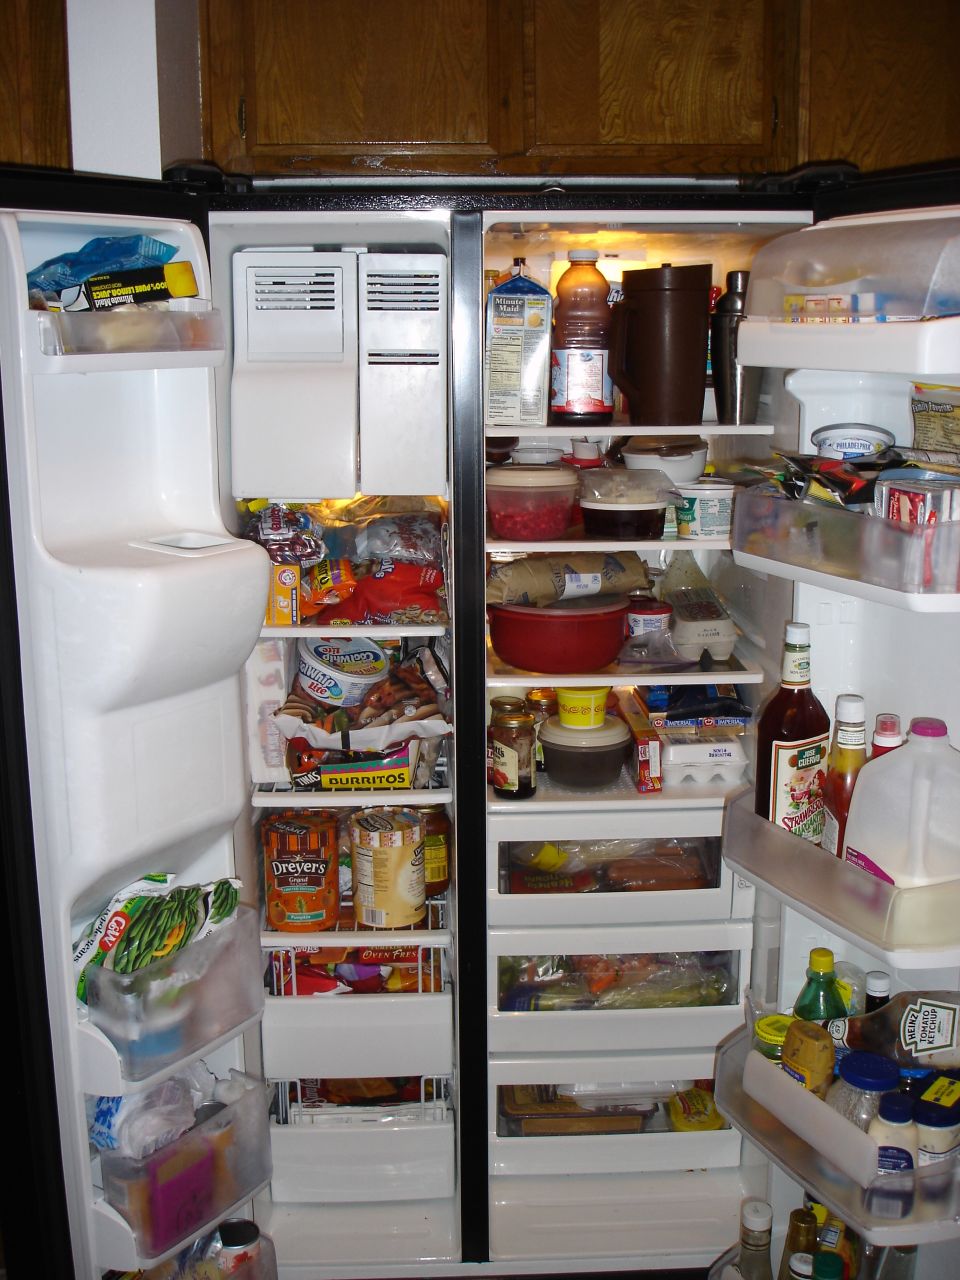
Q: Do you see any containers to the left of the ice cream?
A: Yes, there is a container to the left of the ice cream.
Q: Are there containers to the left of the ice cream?
A: Yes, there is a container to the left of the ice cream.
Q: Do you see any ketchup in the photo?
A: Yes, there is ketchup.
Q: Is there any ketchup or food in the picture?
A: Yes, there is ketchup.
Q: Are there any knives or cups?
A: No, there are no cups or knives.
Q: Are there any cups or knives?
A: No, there are no cups or knives.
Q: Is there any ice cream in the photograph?
A: Yes, there is ice cream.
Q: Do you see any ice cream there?
A: Yes, there is ice cream.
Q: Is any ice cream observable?
A: Yes, there is ice cream.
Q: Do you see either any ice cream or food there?
A: Yes, there is ice cream.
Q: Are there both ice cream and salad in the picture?
A: No, there is ice cream but no salad.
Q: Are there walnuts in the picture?
A: No, there are no walnuts.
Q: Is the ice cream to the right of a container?
A: Yes, the ice cream is to the right of a container.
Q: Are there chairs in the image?
A: No, there are no chairs.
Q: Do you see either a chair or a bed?
A: No, there are no chairs or beds.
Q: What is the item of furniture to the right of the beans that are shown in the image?
A: The piece of furniture is a shelf.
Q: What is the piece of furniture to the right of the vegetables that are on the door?
A: The piece of furniture is a shelf.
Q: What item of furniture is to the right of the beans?
A: The piece of furniture is a shelf.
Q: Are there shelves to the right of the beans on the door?
A: Yes, there is a shelf to the right of the beans.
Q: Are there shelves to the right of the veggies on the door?
A: Yes, there is a shelf to the right of the beans.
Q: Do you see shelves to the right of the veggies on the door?
A: Yes, there is a shelf to the right of the beans.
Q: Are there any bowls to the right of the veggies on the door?
A: No, there is a shelf to the right of the beans.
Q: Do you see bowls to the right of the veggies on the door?
A: No, there is a shelf to the right of the beans.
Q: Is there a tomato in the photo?
A: No, there are no tomatoes.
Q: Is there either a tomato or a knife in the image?
A: No, there are no tomatoes or knives.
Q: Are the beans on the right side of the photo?
A: No, the beans are on the left of the image.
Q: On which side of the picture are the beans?
A: The beans are on the left of the image.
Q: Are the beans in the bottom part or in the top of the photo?
A: The beans are in the bottom of the image.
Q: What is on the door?
A: The beans are on the door.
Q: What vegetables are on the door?
A: The vegetables are beans.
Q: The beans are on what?
A: The beans are on the door.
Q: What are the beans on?
A: The beans are on the door.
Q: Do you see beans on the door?
A: Yes, there are beans on the door.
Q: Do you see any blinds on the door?
A: No, there are beans on the door.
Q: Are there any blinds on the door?
A: No, there are beans on the door.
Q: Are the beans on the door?
A: Yes, the beans are on the door.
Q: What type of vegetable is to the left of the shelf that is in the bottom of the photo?
A: The vegetables are beans.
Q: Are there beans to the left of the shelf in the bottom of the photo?
A: Yes, there are beans to the left of the shelf.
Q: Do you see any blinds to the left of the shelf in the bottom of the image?
A: No, there are beans to the left of the shelf.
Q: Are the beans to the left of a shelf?
A: Yes, the beans are to the left of a shelf.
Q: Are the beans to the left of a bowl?
A: No, the beans are to the left of a shelf.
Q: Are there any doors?
A: Yes, there is a door.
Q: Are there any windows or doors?
A: Yes, there is a door.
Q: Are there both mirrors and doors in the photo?
A: No, there is a door but no mirrors.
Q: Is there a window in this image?
A: No, there are no windows.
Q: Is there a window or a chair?
A: No, there are no windows or chairs.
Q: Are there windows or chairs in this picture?
A: No, there are no windows or chairs.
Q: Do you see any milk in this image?
A: Yes, there is milk.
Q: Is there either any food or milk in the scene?
A: Yes, there is milk.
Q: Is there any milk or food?
A: Yes, there is milk.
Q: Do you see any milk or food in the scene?
A: Yes, there is milk.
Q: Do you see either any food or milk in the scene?
A: Yes, there is milk.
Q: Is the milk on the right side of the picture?
A: Yes, the milk is on the right of the image.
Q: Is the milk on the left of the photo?
A: No, the milk is on the right of the image.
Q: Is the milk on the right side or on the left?
A: The milk is on the right of the image.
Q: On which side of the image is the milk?
A: The milk is on the right of the image.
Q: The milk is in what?
A: The milk is in the freezer.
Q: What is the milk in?
A: The milk is in the freezer.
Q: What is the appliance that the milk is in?
A: The appliance is a refrigerator.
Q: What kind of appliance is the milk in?
A: The milk is in the freezer.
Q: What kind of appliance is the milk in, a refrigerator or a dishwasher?
A: The milk is in a refrigerator.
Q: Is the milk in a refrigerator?
A: Yes, the milk is in a refrigerator.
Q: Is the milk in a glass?
A: No, the milk is in a refrigerator.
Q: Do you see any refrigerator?
A: Yes, there is a refrigerator.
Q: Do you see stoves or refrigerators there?
A: Yes, there is a refrigerator.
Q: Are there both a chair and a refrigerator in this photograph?
A: No, there is a refrigerator but no chairs.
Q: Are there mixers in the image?
A: No, there are no mixers.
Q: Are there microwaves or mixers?
A: No, there are no mixers or microwaves.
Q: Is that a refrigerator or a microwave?
A: That is a refrigerator.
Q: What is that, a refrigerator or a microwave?
A: That is a refrigerator.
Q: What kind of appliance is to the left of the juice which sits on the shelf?
A: The appliance is a refrigerator.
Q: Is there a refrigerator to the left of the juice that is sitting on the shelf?
A: Yes, there is a refrigerator to the left of the juice.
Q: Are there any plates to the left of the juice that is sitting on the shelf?
A: No, there is a refrigerator to the left of the juice.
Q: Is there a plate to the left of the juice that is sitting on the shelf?
A: No, there is a refrigerator to the left of the juice.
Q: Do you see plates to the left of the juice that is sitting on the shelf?
A: No, there is a refrigerator to the left of the juice.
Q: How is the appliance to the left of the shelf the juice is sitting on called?
A: The appliance is a refrigerator.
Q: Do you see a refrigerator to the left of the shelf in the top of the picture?
A: Yes, there is a refrigerator to the left of the shelf.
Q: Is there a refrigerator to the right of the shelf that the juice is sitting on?
A: No, the refrigerator is to the left of the shelf.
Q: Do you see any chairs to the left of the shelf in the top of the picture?
A: No, there is a refrigerator to the left of the shelf.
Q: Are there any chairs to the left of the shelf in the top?
A: No, there is a refrigerator to the left of the shelf.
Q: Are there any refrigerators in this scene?
A: Yes, there is a refrigerator.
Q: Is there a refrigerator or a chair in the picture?
A: Yes, there is a refrigerator.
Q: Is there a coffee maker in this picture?
A: No, there are no coffee makers.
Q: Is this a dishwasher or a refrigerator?
A: This is a refrigerator.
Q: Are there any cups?
A: No, there are no cups.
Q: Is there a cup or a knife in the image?
A: No, there are no cups or knives.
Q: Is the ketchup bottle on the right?
A: Yes, the ketchup bottle is on the right of the image.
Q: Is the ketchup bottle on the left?
A: No, the ketchup bottle is on the right of the image.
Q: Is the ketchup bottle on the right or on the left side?
A: The ketchup bottle is on the right of the image.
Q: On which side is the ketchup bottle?
A: The ketchup bottle is on the right of the image.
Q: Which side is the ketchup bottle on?
A: The ketchup bottle is on the right of the image.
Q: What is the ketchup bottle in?
A: The ketchup bottle is in the fridge.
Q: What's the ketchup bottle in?
A: The ketchup bottle is in the fridge.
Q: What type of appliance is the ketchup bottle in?
A: The ketchup bottle is in the freezer.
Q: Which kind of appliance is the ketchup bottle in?
A: The ketchup bottle is in the freezer.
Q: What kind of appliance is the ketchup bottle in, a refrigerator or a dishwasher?
A: The ketchup bottle is in a refrigerator.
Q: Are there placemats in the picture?
A: No, there are no placemats.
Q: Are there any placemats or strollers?
A: No, there are no placemats or strollers.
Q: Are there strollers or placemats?
A: No, there are no placemats or strollers.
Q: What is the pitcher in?
A: The pitcher is in the refrigerator.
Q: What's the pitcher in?
A: The pitcher is in the refrigerator.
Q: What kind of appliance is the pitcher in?
A: The pitcher is in the refrigerator.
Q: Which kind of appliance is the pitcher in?
A: The pitcher is in the refrigerator.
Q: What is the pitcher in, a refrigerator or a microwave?
A: The pitcher is in a refrigerator.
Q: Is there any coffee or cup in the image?
A: No, there are no cups or coffee.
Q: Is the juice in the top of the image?
A: Yes, the juice is in the top of the image.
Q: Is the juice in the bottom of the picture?
A: No, the juice is in the top of the image.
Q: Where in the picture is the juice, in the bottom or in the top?
A: The juice is in the top of the image.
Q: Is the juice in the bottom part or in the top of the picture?
A: The juice is in the top of the image.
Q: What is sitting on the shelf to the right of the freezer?
A: The juice is sitting on the shelf.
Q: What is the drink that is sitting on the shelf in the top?
A: The drink is juice.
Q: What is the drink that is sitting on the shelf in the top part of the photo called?
A: The drink is juice.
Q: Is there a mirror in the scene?
A: No, there are no mirrors.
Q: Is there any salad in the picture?
A: No, there is no salad.